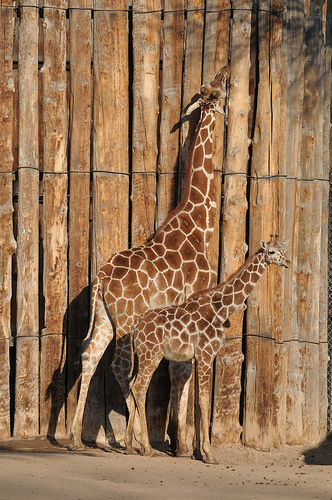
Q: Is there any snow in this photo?
A: Yes, there is snow.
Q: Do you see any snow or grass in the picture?
A: Yes, there is snow.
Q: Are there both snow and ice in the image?
A: No, there is snow but no ice.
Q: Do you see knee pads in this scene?
A: No, there are no knee pads.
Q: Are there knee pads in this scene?
A: No, there are no knee pads.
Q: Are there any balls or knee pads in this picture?
A: No, there are no knee pads or balls.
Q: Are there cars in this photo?
A: No, there are no cars.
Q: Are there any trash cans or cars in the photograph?
A: No, there are no cars or trash cans.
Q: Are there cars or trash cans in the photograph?
A: No, there are no cars or trash cans.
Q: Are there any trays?
A: No, there are no trays.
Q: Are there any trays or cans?
A: No, there are no trays or cans.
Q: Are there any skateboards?
A: No, there are no skateboards.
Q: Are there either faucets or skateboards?
A: No, there are no skateboards or faucets.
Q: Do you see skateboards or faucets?
A: No, there are no skateboards or faucets.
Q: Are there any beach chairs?
A: No, there are no beach chairs.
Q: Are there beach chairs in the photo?
A: No, there are no beach chairs.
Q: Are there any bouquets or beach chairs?
A: No, there are no beach chairs or bouquets.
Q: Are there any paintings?
A: No, there are no paintings.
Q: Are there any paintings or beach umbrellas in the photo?
A: No, there are no paintings or beach umbrellas.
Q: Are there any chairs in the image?
A: No, there are no chairs.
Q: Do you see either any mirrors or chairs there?
A: No, there are no chairs or mirrors.